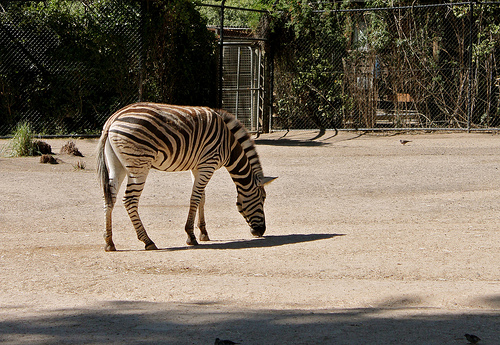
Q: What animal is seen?
A: Zebra.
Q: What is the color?
A: Black and white.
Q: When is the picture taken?
A: Daytime.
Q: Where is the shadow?
A: In the ground.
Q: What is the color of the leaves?
A: Green.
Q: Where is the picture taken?
A: The zoo.